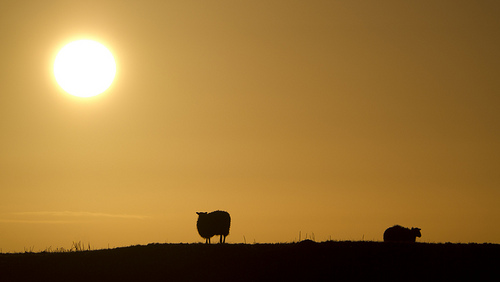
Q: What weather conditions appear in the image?
A: It is cloudless.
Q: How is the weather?
A: It is cloudless.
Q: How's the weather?
A: It is cloudless.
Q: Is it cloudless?
A: Yes, it is cloudless.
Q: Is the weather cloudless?
A: Yes, it is cloudless.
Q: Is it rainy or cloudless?
A: It is cloudless.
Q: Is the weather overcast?
A: No, it is cloudless.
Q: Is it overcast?
A: No, it is cloudless.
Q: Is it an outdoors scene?
A: Yes, it is outdoors.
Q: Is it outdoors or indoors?
A: It is outdoors.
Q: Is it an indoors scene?
A: No, it is outdoors.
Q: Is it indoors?
A: No, it is outdoors.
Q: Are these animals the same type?
A: Yes, all the animals are sheep.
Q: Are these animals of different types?
A: No, all the animals are sheep.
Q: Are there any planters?
A: No, there are no planters.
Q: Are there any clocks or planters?
A: No, there are no planters or clocks.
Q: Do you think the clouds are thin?
A: Yes, the clouds are thin.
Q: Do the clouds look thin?
A: Yes, the clouds are thin.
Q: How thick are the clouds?
A: The clouds are thin.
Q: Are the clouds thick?
A: No, the clouds are thin.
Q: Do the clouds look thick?
A: No, the clouds are thin.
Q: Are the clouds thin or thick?
A: The clouds are thin.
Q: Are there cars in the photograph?
A: No, there are no cars.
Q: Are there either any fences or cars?
A: No, there are no cars or fences.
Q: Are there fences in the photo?
A: No, there are no fences.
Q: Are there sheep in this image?
A: Yes, there is a sheep.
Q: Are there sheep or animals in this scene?
A: Yes, there is a sheep.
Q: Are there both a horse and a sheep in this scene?
A: No, there is a sheep but no horses.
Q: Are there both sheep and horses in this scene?
A: No, there is a sheep but no horses.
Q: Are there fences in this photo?
A: No, there are no fences.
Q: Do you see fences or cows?
A: No, there are no fences or cows.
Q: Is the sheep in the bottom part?
A: Yes, the sheep is in the bottom of the image.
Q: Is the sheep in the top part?
A: No, the sheep is in the bottom of the image.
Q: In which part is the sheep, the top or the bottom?
A: The sheep is in the bottom of the image.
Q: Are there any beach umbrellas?
A: No, there are no beach umbrellas.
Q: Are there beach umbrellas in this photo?
A: No, there are no beach umbrellas.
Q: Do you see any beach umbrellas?
A: No, there are no beach umbrellas.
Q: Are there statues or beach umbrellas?
A: No, there are no beach umbrellas or statues.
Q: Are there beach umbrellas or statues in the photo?
A: No, there are no beach umbrellas or statues.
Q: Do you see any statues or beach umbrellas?
A: No, there are no beach umbrellas or statues.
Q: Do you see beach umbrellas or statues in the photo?
A: No, there are no beach umbrellas or statues.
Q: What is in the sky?
A: The sun is in the sky.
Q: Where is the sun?
A: The sun is in the sky.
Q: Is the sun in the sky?
A: Yes, the sun is in the sky.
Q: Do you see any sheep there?
A: Yes, there is a sheep.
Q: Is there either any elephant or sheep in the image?
A: Yes, there is a sheep.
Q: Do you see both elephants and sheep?
A: No, there is a sheep but no elephants.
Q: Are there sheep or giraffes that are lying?
A: Yes, the sheep is lying.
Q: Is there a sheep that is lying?
A: Yes, there is a sheep that is lying.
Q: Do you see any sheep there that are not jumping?
A: Yes, there is a sheep that is lying .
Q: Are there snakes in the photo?
A: No, there are no snakes.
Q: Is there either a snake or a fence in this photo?
A: No, there are no snakes or fences.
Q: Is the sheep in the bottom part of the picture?
A: Yes, the sheep is in the bottom of the image.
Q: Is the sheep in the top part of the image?
A: No, the sheep is in the bottom of the image.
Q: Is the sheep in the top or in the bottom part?
A: The sheep is in the bottom of the image.